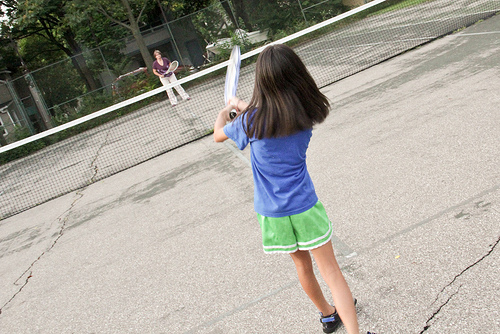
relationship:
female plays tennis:
[210, 35, 366, 334] [159, 14, 409, 332]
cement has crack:
[8, 139, 146, 320] [30, 190, 79, 260]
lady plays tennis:
[151, 50, 192, 107] [122, 10, 372, 331]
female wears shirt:
[210, 35, 366, 334] [226, 104, 329, 220]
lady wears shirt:
[151, 50, 192, 107] [150, 55, 171, 80]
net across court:
[15, 24, 435, 162] [2, 4, 494, 331]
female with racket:
[210, 35, 366, 334] [188, 49, 295, 134]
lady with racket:
[151, 50, 192, 107] [162, 52, 202, 81]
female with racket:
[210, 35, 366, 334] [210, 50, 270, 120]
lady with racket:
[151, 50, 192, 107] [158, 55, 215, 89]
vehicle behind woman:
[84, 60, 159, 116] [126, 49, 223, 128]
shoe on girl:
[284, 300, 352, 324] [189, 49, 430, 298]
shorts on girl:
[251, 186, 336, 267] [197, 51, 385, 331]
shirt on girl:
[175, 82, 341, 204] [149, 43, 409, 323]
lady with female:
[119, 46, 216, 120] [210, 35, 366, 334]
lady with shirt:
[151, 50, 192, 107] [138, 52, 182, 72]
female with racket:
[210, 35, 366, 334] [180, 28, 265, 122]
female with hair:
[210, 35, 366, 334] [244, 45, 326, 142]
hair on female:
[244, 45, 326, 142] [210, 35, 366, 334]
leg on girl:
[285, 246, 340, 331] [245, 37, 367, 330]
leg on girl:
[291, 247, 361, 331] [210, 43, 382, 332]